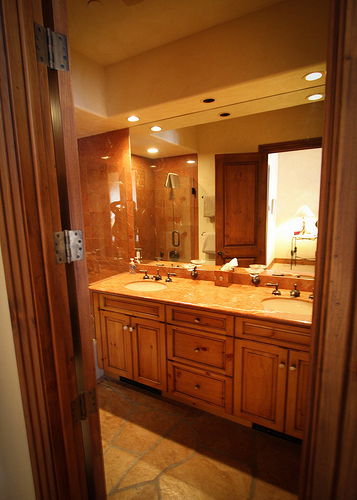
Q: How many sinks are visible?
A: Two.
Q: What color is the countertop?
A: Orange marble.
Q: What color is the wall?
A: Tan.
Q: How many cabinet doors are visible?
A: Seven.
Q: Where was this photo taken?
A: Outside a bathroom.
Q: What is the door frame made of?
A: Wood.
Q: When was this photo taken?
A: Inside, with the lights on.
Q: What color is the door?
A: Brown.